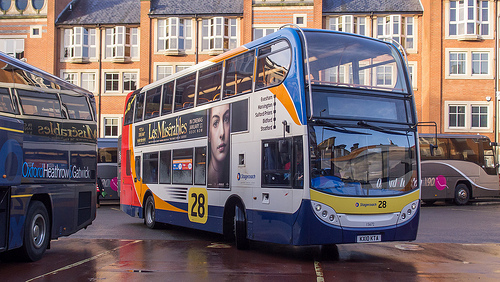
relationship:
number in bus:
[184, 186, 211, 223] [115, 22, 422, 259]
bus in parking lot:
[7, 46, 102, 258] [107, 164, 496, 277]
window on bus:
[303, 40, 398, 88] [115, 22, 422, 259]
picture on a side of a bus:
[206, 101, 231, 188] [115, 22, 422, 259]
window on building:
[449, 0, 489, 34] [3, 0, 494, 165]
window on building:
[449, 0, 489, 34] [0, 0, 499, 138]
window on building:
[447, 106, 469, 131] [3, 1, 497, 206]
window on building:
[466, 97, 493, 134] [3, 0, 494, 165]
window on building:
[446, 49, 468, 78] [38, 57, 494, 187]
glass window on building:
[470, 51, 487, 74] [47, 63, 498, 192]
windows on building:
[445, 47, 496, 77] [54, 72, 494, 186]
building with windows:
[18, 13, 487, 197] [51, 22, 147, 102]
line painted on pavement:
[23, 235, 153, 280] [0, 227, 499, 279]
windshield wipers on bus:
[316, 119, 371, 136] [115, 22, 422, 259]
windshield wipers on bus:
[358, 120, 411, 137] [115, 22, 422, 259]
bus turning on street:
[115, 22, 422, 259] [8, 164, 498, 280]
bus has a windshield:
[115, 22, 422, 259] [311, 121, 418, 196]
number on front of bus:
[372, 190, 393, 210] [115, 22, 422, 259]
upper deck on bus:
[122, 30, 420, 132] [115, 22, 422, 259]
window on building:
[447, 106, 469, 131] [3, 0, 494, 165]